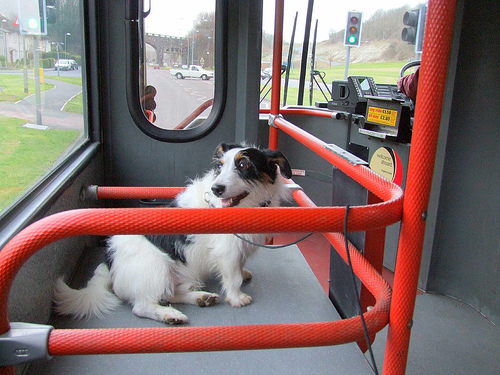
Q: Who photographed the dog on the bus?
A: The pet owner.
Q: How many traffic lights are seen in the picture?
A: 2.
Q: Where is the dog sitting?
A: A seat.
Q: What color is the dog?
A: Black and white.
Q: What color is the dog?
A: White.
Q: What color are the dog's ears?
A: Black.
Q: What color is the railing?
A: Red.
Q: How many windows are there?
A: 3.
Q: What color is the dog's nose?
A: Black.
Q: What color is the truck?
A: White.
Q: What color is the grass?
A: Green.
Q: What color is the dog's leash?
A: Black.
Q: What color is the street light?
A: Green.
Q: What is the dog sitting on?
A: A seat.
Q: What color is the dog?
A: Black and white.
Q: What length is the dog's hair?
A: Long.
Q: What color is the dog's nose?
A: Black.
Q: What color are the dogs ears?
A: Black.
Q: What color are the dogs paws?
A: White.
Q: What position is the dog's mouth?
A: Open.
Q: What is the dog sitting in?
A: Bus.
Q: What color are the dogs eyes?
A: Brown.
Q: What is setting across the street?
A: A white pick-up.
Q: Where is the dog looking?
A: Out the window.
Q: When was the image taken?
A: Daytime.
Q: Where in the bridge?
A: Straight ahead of the bus.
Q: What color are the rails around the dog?
A: Orange.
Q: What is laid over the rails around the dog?
A: A leash.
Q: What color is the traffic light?
A: Green.